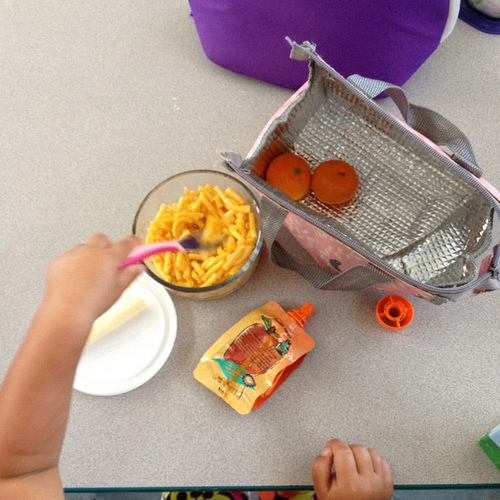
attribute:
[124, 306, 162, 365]
plate — empty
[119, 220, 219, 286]
fork — pink , white 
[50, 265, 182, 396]
container lid — white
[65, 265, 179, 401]
plate — white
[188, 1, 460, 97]
cooler — purple, white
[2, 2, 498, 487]
table — white, gray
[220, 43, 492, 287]
inside — silver 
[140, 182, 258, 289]
mac cheese — orange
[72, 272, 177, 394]
lid — white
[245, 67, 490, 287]
inside — silver